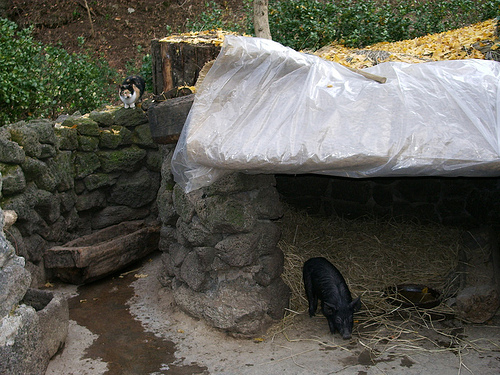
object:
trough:
[40, 219, 161, 285]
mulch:
[146, 28, 245, 145]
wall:
[0, 105, 164, 375]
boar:
[302, 257, 362, 341]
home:
[151, 31, 500, 344]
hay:
[268, 191, 500, 375]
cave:
[150, 19, 500, 342]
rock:
[107, 170, 160, 209]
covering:
[153, 19, 500, 179]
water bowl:
[381, 283, 444, 311]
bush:
[0, 18, 121, 122]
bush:
[237, 0, 499, 53]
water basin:
[42, 220, 158, 285]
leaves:
[159, 18, 499, 94]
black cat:
[118, 75, 147, 109]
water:
[64, 272, 209, 375]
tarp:
[165, 35, 500, 196]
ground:
[5, 250, 500, 375]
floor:
[0, 257, 500, 375]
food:
[61, 219, 144, 250]